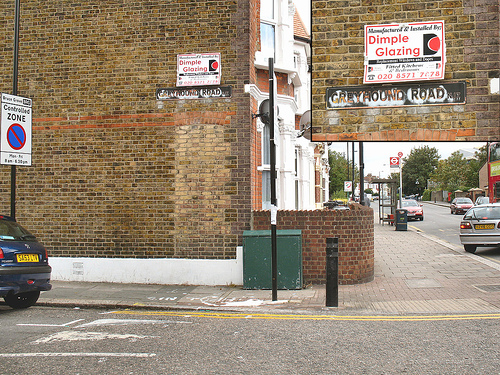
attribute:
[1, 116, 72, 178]
circle — blue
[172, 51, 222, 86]
sign — promotional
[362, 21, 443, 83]
sign — black, red, white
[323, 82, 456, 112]
sign — worn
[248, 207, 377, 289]
brick wall — short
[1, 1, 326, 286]
building — brick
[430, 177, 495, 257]
car — white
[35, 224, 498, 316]
sidewalk — brick paved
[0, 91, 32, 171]
sign — informational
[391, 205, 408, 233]
trashcan — green 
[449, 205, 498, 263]
car — silver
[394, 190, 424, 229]
car — silver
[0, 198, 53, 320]
car — silver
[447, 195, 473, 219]
car — silver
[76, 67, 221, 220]
brick — brown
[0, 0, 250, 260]
wall — large, brown, brick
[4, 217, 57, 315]
car — blue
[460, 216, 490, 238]
license — black and yellow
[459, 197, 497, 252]
car — blue, parked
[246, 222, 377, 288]
wall — short, brick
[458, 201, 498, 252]
car — silver , red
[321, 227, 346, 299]
black post — short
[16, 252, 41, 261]
license plate — yellow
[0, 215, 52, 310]
car — blue